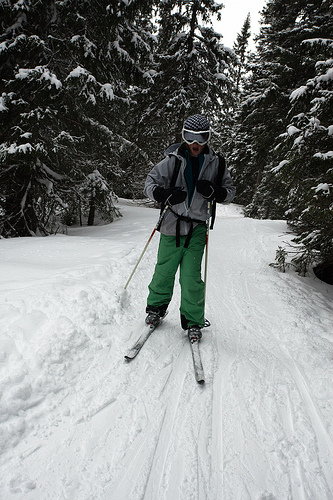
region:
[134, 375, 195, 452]
lines in the white snow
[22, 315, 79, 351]
small mound in the snow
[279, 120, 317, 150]
snow on the tree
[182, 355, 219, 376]
snow covered snow skis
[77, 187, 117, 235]
large trunk of snow covered tree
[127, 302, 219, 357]
black shoes on the skis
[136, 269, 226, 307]
wrinkles in green ski pants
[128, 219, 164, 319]
large silver pole in snow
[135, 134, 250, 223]
man wearing black and gray jacket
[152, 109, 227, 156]
large blue and silver goggles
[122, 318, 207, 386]
A pair of skis on a person skiing through snow.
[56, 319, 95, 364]
Large amount of snow next to a skier.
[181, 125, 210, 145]
Large pair of goggles on a persons face.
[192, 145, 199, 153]
Open mouth on a person who is skiing.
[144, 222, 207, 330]
Green ski pants on a person skiing.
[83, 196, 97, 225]
Small base of a pine tree sticking out of the snow.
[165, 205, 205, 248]
Black strap tied around a person with green snow pants on.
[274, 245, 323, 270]
Thin pine tree branches covered in snow.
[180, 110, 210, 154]
Head of a person with goggles on and their mouth open.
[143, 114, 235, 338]
A person with goggles on skiing through the snow.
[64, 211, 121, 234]
snow around the base of tree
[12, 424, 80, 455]
lines in the white snow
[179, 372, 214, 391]
edge of snow skis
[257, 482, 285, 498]
small hole in snow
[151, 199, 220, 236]
black string around skier's waist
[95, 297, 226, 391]
snow covered skis on man's feet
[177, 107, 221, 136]
black and white hat on man's head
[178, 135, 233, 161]
man's mouth open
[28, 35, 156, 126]
large cluster of tall green trees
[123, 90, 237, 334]
skier with back pack on his back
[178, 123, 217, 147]
a ski mask on a face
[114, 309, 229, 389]
snow skis on feet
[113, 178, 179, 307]
ski pole in a hand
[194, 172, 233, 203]
glove on a hand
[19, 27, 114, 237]
trees that are snow covered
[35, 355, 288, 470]
the tracks of snow skis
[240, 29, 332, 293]
trees at the edge of the ski run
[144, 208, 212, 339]
a pair of green ski pants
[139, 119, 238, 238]
a person wearing a grey coat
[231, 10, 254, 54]
the top of a tree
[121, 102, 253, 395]
person skiing in white snow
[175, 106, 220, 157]
person wearing white ski mask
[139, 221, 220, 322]
person wearing green pants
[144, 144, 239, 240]
person wearing gray jacket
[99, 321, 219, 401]
black snow covered skis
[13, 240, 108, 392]
soft white snow with ski tracks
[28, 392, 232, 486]
soft white snow with ski tracks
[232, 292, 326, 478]
soft white snow wit ski tracks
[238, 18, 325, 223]
green trees covered with white snow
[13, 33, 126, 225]
green trees covered with white snow